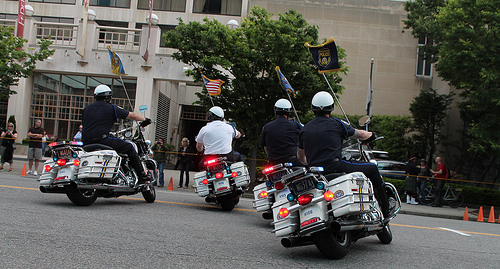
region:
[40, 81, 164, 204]
policeman on large white motorcycle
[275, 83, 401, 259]
policeman on large white motorcycle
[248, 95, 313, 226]
policeman on large white motorcycle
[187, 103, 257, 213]
policeman on large white motorcycle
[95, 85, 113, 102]
white helmet on policeman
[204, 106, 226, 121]
white helmet on policeman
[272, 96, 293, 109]
white helmet on policeman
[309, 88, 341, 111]
white helmet on policeman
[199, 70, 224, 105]
American flag flying near building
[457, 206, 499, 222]
orange traffic cones on street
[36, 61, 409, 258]
four police officers on motorcycles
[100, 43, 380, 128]
multiple flags on police motorcycles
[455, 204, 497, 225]
orange safety cones on the side of a street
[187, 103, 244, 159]
white short sleeve shirt on a policeman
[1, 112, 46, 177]
spectators watching a parade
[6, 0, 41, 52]
red flag on white building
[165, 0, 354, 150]
large green bush in front of a tan building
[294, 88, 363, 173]
police officer with a dark short sleeved shirt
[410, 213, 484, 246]
white and orange painted lines on gray pavement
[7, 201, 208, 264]
gray pavement on a street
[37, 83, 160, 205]
A policeman is riding a motorcycle.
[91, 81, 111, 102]
The color of a policeman's helmet is white and black.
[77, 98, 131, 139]
The color of a policeman's shirt is black.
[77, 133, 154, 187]
The color of a policeman's pants is black.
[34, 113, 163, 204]
The colors of a motorcycle are white, black, red, and green.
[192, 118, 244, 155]
A policeman is wearing a white shirt.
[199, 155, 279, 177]
The brake lights are light on two motorcycles.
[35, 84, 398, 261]
Four motorcycles are making a turn.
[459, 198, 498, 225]
Three orange cones are by a road.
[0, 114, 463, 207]
People are in the background.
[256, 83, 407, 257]
Motorcycle officers on the road.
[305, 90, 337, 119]
Black and white helmet on officer.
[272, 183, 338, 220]
Orange tail lights on motorcycle.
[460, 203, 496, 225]
Orange cones on side of road.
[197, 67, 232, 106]
Red, white, and blue flag in front of building.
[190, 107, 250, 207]
Man wearing white shirt.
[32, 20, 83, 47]
Brown railing on building.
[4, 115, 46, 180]
People standing on road.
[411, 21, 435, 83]
Window in side of the building.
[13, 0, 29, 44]
Red sign on building.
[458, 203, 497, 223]
three orange traffic cones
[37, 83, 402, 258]
four motorcycles on the road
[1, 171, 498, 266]
yellow line on the road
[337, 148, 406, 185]
parked vehicles beside the building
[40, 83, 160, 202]
man wearing a white helmet riding a motorcycle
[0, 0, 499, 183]
concrete building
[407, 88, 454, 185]
small tree in front of building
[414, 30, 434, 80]
part of a window on the front of a building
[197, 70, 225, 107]
American Flag on a silver flag pole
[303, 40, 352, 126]
navy blue and yellow flag